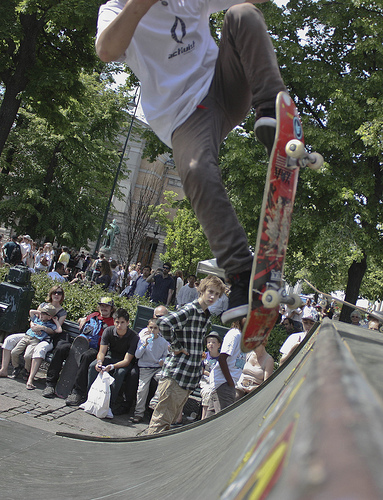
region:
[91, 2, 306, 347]
a guy showing tricks in his skateboard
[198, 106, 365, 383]
a skateboard in the air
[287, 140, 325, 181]
wheels of the skateboard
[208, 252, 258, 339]
a black shoe with white sole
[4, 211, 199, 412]
spectators in the skateboarding show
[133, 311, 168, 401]
a kid with bottled water in his mouth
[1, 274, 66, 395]
a lady in sunglasses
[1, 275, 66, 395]
a lady holding a kid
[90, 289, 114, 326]
a smiling guy wearing a hat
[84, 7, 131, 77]
an elbow of a guy in his skateboard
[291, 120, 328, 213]
White wheels on skateboard.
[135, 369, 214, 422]
Person wearing tan pants.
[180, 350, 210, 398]
Person wearing black and white shirt.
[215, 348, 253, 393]
Person wearing white t-shirt.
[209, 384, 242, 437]
Person wearing gray pants.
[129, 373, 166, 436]
Person wearing tan pants.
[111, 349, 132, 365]
Person wearing black shirt.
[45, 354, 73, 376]
Person wearing black pants.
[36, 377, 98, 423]
Person wearing dark tennis shoes.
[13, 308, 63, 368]
Lady holding child on bench.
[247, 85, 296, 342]
red skateboard with designs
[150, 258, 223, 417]
boy watching the skateboarder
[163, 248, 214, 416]
boy wearing black plaid shirt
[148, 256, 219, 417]
boy wearing tan pants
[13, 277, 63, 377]
woman sitting on a bench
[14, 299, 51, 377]
kid wearing dark sunglasses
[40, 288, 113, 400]
man wearing red shirt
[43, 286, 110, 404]
man with skateboard between legs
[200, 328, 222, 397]
little girl wearing a hat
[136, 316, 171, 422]
boy wearing white shirt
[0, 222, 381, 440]
reasonably large crowd of people @ outdoor event that includes skate demos+food+junk stands, @ the very least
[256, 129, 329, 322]
four dusty white skateboard wheels held together by silvertone metal axles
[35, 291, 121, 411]
definitely not teenager sits w/ black skateboard between black jeaned legs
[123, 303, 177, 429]
nearly hairless older man watches @ least one child drinking from a blue container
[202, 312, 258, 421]
some long dark hair, white t-shirt w/ cartoon, greige cargo pants, long sleeved shirt beneath t-shirt: all that's visible of guy directly beneath skater's foot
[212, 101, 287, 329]
skater wears canvas black trainers/sneakers/skate shoes w/ white soles that have a thin red line @ top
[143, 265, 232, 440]
maybe sixteen year old dude, dressed in post-grunge items & w/ longish messyish blondish hair, concentrating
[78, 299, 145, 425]
the serious face of a guy in black w/ white armband, white plastic bag &, i believe, cellphone, who looks a bit like keanu reeves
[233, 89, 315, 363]
red+black skateboard underside, w/ dents, minor gouges, wear, a few stickers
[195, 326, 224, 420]
little kid in serious little black hat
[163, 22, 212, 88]
a small text written on shirt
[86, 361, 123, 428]
a white bag on road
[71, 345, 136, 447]
a white bag holding by boy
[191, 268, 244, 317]
face of the person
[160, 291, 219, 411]
shirt of the person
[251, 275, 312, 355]
wheel of the machine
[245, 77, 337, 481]
a small skating machine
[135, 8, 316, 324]
a man skatting in air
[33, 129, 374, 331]
a group of trees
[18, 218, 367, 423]
a group of people sitting around